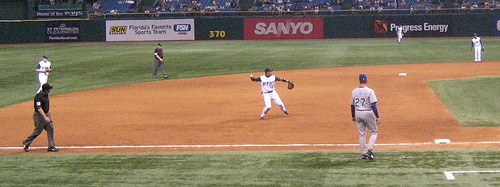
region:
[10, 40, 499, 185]
the baseball field during the game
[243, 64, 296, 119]
the player getting ready to throw the ball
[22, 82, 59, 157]
the referee watching the game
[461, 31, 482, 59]
the player standing around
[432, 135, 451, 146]
the base that nobody is standing by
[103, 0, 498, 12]
the people watching the game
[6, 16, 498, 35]
the wall at the end of the field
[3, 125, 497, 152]
the white line along the field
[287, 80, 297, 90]
the mitt on the man's hand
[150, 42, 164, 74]
another referee in the game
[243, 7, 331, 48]
the text is white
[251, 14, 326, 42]
the sign says Sanyo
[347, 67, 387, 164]
the man is standing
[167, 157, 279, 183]
the turf is green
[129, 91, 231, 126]
the dirt is orange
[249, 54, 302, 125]
the man is pitching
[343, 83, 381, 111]
the shirt is white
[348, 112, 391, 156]
the pants are white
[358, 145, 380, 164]
the shoes are black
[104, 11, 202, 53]
the sign is white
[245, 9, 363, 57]
a red sanyo sign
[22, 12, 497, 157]
seven baseball players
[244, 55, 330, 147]
a baseball player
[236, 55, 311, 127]
a baseball player with a baseball and glove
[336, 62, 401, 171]
the number twenty seven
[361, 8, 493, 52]
a progress energy sign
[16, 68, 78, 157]
a man wearing all black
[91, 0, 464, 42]
crowd stands with people sitting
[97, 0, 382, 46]
people sitting watching the baseball game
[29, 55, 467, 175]
green and brown baseball field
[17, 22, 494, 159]
Players on the field playing baseball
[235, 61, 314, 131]
Baseball player is about to throw a ball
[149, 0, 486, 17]
Crowd is in the background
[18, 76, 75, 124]
Person is wearing a black shirt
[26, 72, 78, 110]
Person is wearing a black cap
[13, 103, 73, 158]
Person is wearing gray pants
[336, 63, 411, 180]
Baseball players outfit is gray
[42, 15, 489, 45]
Advertisement signs are in the background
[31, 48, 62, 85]
Player in the background is wearing a white outfit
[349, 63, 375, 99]
Baseball player is wearing a blue cap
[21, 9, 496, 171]
Picture of a baseball game.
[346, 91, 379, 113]
The number 27 on player's uniform.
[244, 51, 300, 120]
Player getting ready to throw ball.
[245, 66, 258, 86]
Baseball in player's right hand.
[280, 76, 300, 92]
Baseball glove in player's left hand.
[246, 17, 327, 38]
The word SANYO in white letters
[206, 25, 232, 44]
The number 370 in yellow letters.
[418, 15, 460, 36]
The word Energy in white letters.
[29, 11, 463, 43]
Different advertising along wall.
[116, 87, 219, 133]
Dirt of the baseball field.